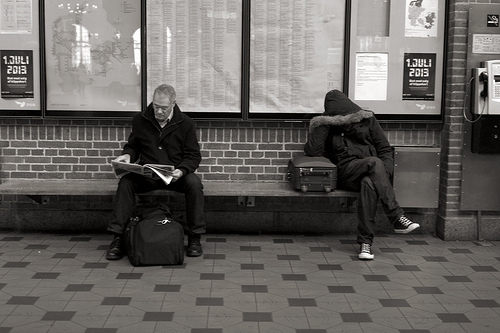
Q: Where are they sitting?
A: On a bench.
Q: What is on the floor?
A: Tiles.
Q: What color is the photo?
A: Black and white.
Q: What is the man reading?
A: Magazine.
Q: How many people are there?
A: Two.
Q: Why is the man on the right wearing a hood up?
A: Sleeping.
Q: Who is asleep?
A: Person on right.